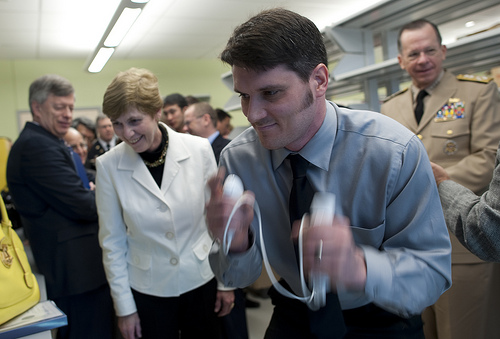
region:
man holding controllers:
[188, 2, 454, 334]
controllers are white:
[211, 171, 338, 311]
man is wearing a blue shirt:
[202, 92, 456, 317]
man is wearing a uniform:
[363, 17, 498, 337]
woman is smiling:
[80, 67, 251, 337]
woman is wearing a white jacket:
[83, 116, 248, 319]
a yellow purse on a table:
[1, 191, 48, 333]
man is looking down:
[5, 67, 121, 332]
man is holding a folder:
[63, 143, 101, 199]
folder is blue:
[67, 143, 99, 196]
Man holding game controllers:
[192, 10, 447, 316]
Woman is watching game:
[82, 71, 254, 336]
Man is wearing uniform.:
[362, 11, 498, 201]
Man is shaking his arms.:
[203, 157, 378, 312]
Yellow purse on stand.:
[0, 191, 74, 337]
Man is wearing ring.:
[310, 233, 341, 276]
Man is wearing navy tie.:
[280, 146, 348, 337]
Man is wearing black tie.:
[408, 84, 433, 131]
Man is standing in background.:
[378, 9, 498, 337]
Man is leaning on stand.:
[7, 74, 133, 337]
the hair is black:
[219, 17, 333, 84]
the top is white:
[94, 148, 222, 304]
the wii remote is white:
[291, 204, 333, 297]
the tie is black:
[263, 158, 313, 215]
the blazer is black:
[17, 136, 106, 298]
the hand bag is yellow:
[0, 208, 41, 305]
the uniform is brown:
[389, 84, 497, 178]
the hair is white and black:
[24, 74, 81, 104]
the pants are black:
[138, 300, 251, 336]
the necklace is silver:
[142, 158, 172, 170]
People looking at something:
[5, 7, 498, 335]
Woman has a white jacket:
[89, 69, 251, 336]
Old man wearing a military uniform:
[379, 14, 499, 337]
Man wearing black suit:
[0, 69, 120, 334]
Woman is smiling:
[91, 64, 252, 336]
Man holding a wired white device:
[196, 11, 468, 336]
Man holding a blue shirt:
[202, 8, 467, 337]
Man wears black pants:
[213, 13, 445, 336]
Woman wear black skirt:
[85, 62, 260, 336]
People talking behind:
[165, 87, 234, 152]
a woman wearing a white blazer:
[90, 63, 252, 337]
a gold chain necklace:
[128, 130, 183, 172]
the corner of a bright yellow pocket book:
[3, 200, 39, 332]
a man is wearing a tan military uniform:
[376, 17, 499, 334]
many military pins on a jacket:
[431, 90, 471, 125]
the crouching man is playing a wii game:
[208, 98, 455, 316]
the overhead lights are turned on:
[86, 2, 156, 72]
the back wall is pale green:
[3, 54, 278, 149]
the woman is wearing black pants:
[130, 265, 249, 337]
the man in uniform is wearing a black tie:
[413, 86, 433, 126]